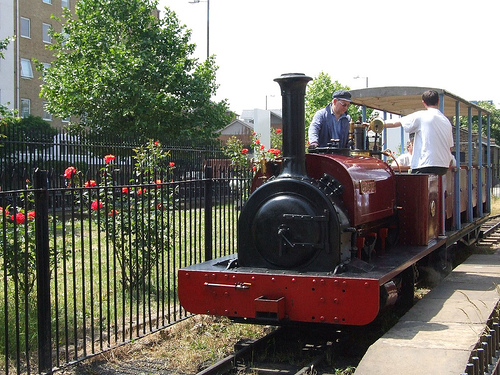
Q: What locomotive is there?
A: Train.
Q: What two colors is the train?
A: Red and black.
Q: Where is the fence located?
A: Next to the train.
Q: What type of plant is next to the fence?
A: Rose bush.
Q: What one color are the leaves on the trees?
A: Green.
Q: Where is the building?
A: Behind the trees.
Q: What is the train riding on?
A: Train tracks.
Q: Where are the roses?
A: Behind the fence.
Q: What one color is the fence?
A: Black.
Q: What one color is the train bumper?
A: Red.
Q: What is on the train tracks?
A: Train.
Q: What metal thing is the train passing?
A: Metal gate.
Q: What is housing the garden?
A: Fence.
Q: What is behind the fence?
A: Red rose bushes.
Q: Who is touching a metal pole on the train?
A: Man in white shirt.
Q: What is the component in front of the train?
A: Engine.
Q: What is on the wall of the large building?
A: Windows.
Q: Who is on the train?
A: Three men.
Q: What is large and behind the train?
A: Buildings.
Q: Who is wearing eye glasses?
A: Man in blue cap.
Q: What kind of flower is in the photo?
A: Roses.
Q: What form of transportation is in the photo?
A: Train.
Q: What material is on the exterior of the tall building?
A: Brick.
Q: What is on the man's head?
A: Hat.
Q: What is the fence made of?
A: Iron.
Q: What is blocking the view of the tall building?
A: Tree.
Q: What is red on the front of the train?
A: Grill.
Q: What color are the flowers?
A: Red.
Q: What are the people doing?
A: Riding a train.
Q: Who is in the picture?
A: Two men.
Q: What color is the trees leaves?
A: Green.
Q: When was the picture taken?
A: During the day.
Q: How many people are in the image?
A: Two.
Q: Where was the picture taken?
A: While the people were riding the train.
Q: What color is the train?
A: Red and black.